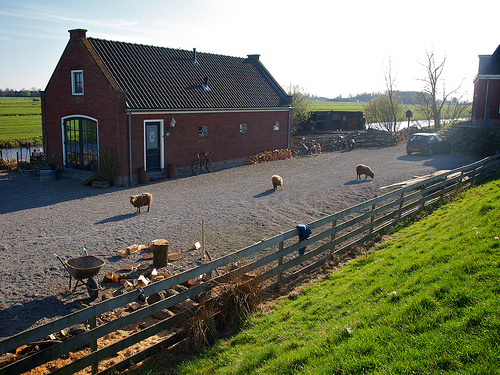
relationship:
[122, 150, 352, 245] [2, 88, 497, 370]
farm in country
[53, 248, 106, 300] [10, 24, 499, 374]
wheelbarrow on farm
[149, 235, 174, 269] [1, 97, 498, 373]
logs on ground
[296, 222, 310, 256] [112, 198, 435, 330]
jacket on fence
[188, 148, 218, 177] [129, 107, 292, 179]
bicycle next to wall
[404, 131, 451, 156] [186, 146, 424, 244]
car in gravel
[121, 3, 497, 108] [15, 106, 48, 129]
cloud in sky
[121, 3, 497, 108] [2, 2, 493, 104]
cloud in sky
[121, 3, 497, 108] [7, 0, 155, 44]
cloud in sky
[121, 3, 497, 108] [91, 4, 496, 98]
cloud in sky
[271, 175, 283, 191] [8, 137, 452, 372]
animal on road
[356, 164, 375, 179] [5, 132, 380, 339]
animal on road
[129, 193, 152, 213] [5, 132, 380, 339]
animal on road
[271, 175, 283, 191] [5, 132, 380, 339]
animal on road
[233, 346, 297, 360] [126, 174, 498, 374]
part of grass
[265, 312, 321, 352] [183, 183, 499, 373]
part of green grass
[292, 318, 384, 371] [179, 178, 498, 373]
part of grass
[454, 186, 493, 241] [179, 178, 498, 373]
part of grass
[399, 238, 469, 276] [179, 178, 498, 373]
part of grass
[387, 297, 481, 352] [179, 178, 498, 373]
part of grass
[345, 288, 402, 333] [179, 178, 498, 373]
part of grass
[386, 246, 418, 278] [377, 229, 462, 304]
part of grass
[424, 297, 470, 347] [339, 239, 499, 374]
part of grass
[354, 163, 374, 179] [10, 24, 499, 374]
animal on farm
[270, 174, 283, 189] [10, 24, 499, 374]
animal on farm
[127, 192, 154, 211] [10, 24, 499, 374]
animal on farm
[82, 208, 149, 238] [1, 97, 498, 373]
shadow on ground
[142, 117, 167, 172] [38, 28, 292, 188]
door on house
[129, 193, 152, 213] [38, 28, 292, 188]
animal in front of house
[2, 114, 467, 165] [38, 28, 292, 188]
creek behind a house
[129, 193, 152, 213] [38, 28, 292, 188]
animal near house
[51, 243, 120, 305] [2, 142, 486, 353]
wheelbarrow on gravel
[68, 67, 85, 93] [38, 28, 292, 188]
window on house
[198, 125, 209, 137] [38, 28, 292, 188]
window on house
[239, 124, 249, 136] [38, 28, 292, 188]
window on house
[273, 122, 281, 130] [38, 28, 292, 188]
window on house